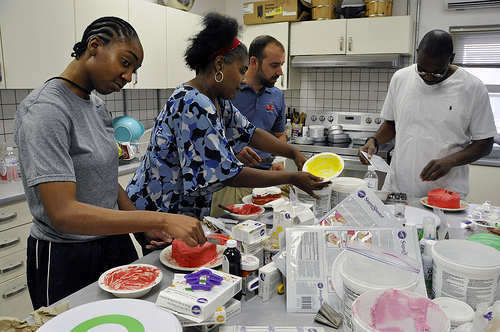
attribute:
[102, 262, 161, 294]
container — stained, white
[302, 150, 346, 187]
container — yellow, stained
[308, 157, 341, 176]
stain — yellow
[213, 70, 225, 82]
earring — shiny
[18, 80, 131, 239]
t-shirt — grey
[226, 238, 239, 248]
bottle top — white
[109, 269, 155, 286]
stain — red, pink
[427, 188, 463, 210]
cake — pink, small, iced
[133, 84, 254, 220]
top — blue, black, white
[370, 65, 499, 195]
t-shirt — white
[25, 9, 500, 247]
people — cooking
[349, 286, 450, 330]
bucket — plastic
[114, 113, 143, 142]
bowl — plastic, blue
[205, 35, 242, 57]
hair band — red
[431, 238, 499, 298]
plastic bowl — tall, white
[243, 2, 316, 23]
carboard box — opened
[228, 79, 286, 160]
shirt — blue